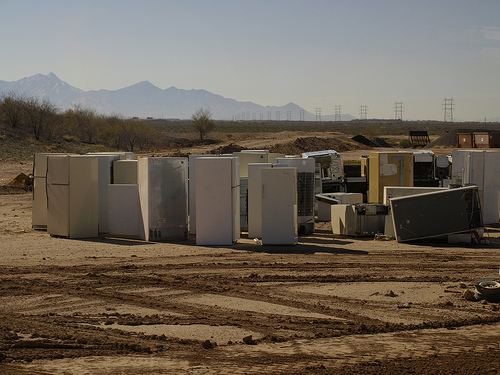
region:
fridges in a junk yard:
[31, 128, 496, 266]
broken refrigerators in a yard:
[29, 129, 496, 279]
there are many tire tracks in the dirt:
[3, 263, 491, 373]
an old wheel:
[471, 271, 498, 304]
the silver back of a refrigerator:
[141, 153, 191, 250]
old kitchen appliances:
[19, 124, 499, 276]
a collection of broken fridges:
[15, 126, 497, 267]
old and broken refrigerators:
[19, 139, 498, 264]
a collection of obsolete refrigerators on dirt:
[21, 140, 498, 270]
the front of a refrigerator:
[40, 152, 82, 242]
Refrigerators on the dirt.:
[21, 99, 433, 329]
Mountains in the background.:
[117, 27, 383, 177]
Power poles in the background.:
[271, 74, 475, 165]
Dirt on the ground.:
[117, 267, 307, 356]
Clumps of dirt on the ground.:
[113, 241, 229, 353]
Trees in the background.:
[152, 101, 242, 135]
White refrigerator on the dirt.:
[23, 133, 125, 255]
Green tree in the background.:
[128, 87, 240, 156]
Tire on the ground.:
[442, 239, 497, 299]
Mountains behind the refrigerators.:
[41, 63, 486, 127]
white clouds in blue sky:
[18, 15, 74, 62]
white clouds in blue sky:
[105, 20, 156, 60]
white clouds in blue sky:
[181, 20, 236, 82]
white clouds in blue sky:
[266, 10, 323, 65]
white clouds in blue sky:
[357, 16, 462, 72]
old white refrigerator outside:
[196, 155, 236, 251]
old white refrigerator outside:
[110, 157, 162, 239]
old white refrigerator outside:
[60, 161, 96, 218]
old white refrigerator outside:
[257, 155, 297, 251]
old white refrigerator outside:
[459, 150, 491, 204]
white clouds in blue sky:
[7, 9, 69, 39]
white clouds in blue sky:
[54, 32, 110, 84]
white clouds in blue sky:
[239, 13, 282, 87]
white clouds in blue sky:
[288, 15, 338, 86]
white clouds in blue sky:
[346, 15, 386, 82]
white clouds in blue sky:
[391, 15, 436, 80]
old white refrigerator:
[186, 155, 246, 241]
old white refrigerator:
[114, 157, 170, 228]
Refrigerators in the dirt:
[58, 117, 438, 254]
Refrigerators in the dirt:
[114, 137, 269, 218]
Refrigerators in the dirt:
[323, 163, 430, 259]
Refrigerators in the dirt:
[448, 151, 490, 234]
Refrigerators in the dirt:
[32, 138, 116, 247]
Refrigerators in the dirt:
[120, 152, 192, 243]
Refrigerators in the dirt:
[189, 136, 285, 224]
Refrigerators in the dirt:
[316, 158, 377, 223]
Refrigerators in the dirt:
[413, 135, 475, 227]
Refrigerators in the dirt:
[197, 150, 322, 197]